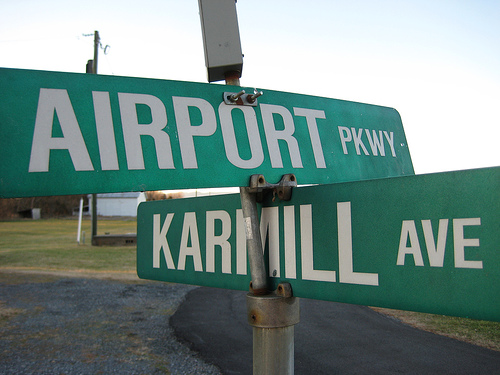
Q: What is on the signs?
A: Street names.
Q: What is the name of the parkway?
A: Airport Parkway.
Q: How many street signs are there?
A: Two.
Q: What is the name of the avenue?
A: Karmill Avenue.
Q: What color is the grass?
A: Green.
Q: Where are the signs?
A: On a post.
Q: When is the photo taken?
A: Daytime.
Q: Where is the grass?
A: Around the asphalt.